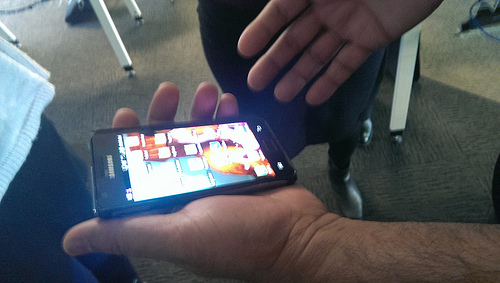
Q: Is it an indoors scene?
A: Yes, it is indoors.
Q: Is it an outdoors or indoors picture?
A: It is indoors.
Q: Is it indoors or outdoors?
A: It is indoors.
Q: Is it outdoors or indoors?
A: It is indoors.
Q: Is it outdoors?
A: No, it is indoors.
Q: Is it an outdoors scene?
A: No, it is indoors.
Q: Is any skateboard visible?
A: No, there are no skateboards.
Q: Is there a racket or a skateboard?
A: No, there are no skateboards or rackets.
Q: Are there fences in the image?
A: No, there are no fences.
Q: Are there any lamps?
A: Yes, there is a lamp.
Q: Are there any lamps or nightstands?
A: Yes, there is a lamp.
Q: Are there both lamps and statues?
A: No, there is a lamp but no statues.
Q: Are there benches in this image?
A: No, there are no benches.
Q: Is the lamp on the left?
A: Yes, the lamp is on the left of the image.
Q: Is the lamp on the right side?
A: No, the lamp is on the left of the image.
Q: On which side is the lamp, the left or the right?
A: The lamp is on the left of the image.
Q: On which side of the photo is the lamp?
A: The lamp is on the left of the image.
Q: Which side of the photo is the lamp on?
A: The lamp is on the left of the image.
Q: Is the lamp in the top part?
A: Yes, the lamp is in the top of the image.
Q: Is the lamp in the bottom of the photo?
A: No, the lamp is in the top of the image.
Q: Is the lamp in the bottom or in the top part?
A: The lamp is in the top of the image.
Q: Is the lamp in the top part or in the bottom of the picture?
A: The lamp is in the top of the image.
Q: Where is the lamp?
A: The lamp is on the floor.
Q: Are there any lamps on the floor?
A: Yes, there is a lamp on the floor.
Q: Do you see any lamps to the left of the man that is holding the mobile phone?
A: Yes, there is a lamp to the left of the man.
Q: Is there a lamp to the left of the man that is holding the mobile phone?
A: Yes, there is a lamp to the left of the man.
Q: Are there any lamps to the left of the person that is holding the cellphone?
A: Yes, there is a lamp to the left of the man.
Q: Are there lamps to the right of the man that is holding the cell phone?
A: No, the lamp is to the left of the man.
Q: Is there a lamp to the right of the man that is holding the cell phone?
A: No, the lamp is to the left of the man.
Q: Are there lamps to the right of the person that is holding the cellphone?
A: No, the lamp is to the left of the man.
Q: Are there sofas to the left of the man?
A: No, there is a lamp to the left of the man.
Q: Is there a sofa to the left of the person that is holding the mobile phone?
A: No, there is a lamp to the left of the man.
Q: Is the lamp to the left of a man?
A: Yes, the lamp is to the left of a man.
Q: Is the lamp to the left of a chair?
A: No, the lamp is to the left of a man.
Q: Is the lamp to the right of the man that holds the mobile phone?
A: No, the lamp is to the left of the man.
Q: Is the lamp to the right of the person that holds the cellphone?
A: No, the lamp is to the left of the man.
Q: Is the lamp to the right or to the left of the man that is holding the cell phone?
A: The lamp is to the left of the man.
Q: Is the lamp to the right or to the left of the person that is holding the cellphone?
A: The lamp is to the left of the man.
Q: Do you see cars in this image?
A: No, there are no cars.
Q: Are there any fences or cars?
A: No, there are no cars or fences.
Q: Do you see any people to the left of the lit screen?
A: Yes, there is a person to the left of the screen.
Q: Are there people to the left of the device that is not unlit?
A: Yes, there is a person to the left of the screen.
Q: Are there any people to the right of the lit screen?
A: No, the person is to the left of the screen.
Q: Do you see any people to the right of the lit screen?
A: No, the person is to the left of the screen.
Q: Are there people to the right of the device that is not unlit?
A: No, the person is to the left of the screen.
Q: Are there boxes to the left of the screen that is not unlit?
A: No, there is a person to the left of the screen.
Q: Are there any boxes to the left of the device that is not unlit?
A: No, there is a person to the left of the screen.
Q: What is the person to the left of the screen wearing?
A: The person is wearing a sweater.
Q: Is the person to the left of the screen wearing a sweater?
A: Yes, the person is wearing a sweater.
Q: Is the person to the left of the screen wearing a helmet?
A: No, the person is wearing a sweater.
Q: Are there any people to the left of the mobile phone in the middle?
A: Yes, there is a person to the left of the cell phone.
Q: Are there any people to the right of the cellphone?
A: No, the person is to the left of the cellphone.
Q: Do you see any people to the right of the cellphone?
A: No, the person is to the left of the cellphone.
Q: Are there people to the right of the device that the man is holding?
A: No, the person is to the left of the cellphone.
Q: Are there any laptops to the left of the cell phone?
A: No, there is a person to the left of the cell phone.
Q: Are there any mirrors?
A: No, there are no mirrors.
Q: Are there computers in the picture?
A: No, there are no computers.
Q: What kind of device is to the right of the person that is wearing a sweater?
A: The device is a screen.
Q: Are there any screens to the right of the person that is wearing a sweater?
A: Yes, there is a screen to the right of the person.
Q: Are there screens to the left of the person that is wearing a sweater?
A: No, the screen is to the right of the person.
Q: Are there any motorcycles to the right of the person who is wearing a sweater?
A: No, there is a screen to the right of the person.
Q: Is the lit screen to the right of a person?
A: Yes, the screen is to the right of a person.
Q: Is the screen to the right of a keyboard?
A: No, the screen is to the right of a person.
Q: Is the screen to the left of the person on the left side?
A: No, the screen is to the right of the person.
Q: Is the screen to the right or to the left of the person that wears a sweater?
A: The screen is to the right of the person.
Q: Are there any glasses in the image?
A: No, there are no glasses.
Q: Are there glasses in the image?
A: No, there are no glasses.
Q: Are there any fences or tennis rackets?
A: No, there are no fences or tennis rackets.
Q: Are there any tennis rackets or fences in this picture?
A: No, there are no fences or tennis rackets.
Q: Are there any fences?
A: No, there are no fences.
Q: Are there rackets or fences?
A: No, there are no fences or rackets.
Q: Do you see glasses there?
A: No, there are no glasses.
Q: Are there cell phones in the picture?
A: Yes, there is a cell phone.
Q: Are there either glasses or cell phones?
A: Yes, there is a cell phone.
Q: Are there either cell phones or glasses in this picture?
A: Yes, there is a cell phone.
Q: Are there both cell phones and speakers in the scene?
A: No, there is a cell phone but no speakers.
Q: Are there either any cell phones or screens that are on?
A: Yes, the cell phone is on.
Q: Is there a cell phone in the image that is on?
A: Yes, there is a cell phone that is on.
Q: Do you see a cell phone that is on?
A: Yes, there is a cell phone that is on.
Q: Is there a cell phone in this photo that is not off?
A: Yes, there is a cell phone that is on.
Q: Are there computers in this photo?
A: No, there are no computers.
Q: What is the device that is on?
A: The device is a cell phone.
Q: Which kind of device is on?
A: The device is a cell phone.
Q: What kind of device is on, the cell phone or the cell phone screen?
A: The cell phone is on.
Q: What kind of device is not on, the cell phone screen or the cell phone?
A: The screen is not on.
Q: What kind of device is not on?
A: The device is a screen.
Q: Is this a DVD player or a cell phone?
A: This is a cell phone.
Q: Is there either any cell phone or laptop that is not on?
A: No, there is a cell phone but it is on.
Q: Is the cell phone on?
A: Yes, the cell phone is on.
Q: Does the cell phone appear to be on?
A: Yes, the cell phone is on.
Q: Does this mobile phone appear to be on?
A: Yes, the mobile phone is on.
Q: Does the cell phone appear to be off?
A: No, the cell phone is on.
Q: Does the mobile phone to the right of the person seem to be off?
A: No, the mobile phone is on.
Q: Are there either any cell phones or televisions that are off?
A: No, there is a cell phone but it is on.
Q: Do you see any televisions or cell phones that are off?
A: No, there is a cell phone but it is on.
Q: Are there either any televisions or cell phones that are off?
A: No, there is a cell phone but it is on.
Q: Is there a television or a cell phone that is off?
A: No, there is a cell phone but it is on.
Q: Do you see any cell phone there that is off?
A: No, there is a cell phone but it is on.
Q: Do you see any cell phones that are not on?
A: No, there is a cell phone but it is on.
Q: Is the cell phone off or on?
A: The cell phone is on.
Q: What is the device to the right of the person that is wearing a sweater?
A: The device is a cell phone.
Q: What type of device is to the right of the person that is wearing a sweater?
A: The device is a cell phone.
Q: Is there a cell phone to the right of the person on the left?
A: Yes, there is a cell phone to the right of the person.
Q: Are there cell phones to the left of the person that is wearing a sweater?
A: No, the cell phone is to the right of the person.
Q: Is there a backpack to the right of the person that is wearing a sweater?
A: No, there is a cell phone to the right of the person.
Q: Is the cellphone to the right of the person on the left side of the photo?
A: Yes, the cellphone is to the right of the person.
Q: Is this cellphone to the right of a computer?
A: No, the cellphone is to the right of the person.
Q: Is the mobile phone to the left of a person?
A: No, the mobile phone is to the right of a person.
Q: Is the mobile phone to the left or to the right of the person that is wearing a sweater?
A: The mobile phone is to the right of the person.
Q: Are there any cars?
A: No, there are no cars.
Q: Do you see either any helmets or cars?
A: No, there are no cars or helmets.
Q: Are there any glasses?
A: No, there are no glasses.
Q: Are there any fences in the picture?
A: No, there are no fences.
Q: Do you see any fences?
A: No, there are no fences.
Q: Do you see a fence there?
A: No, there are no fences.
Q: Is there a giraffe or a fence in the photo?
A: No, there are no fences or giraffes.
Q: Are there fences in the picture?
A: No, there are no fences.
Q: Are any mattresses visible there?
A: No, there are no mattresses.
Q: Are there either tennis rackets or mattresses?
A: No, there are no mattresses or tennis rackets.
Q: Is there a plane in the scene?
A: No, there are no airplanes.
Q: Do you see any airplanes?
A: No, there are no airplanes.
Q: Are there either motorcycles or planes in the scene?
A: No, there are no planes or motorcycles.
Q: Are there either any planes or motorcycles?
A: No, there are no planes or motorcycles.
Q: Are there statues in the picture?
A: No, there are no statues.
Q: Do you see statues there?
A: No, there are no statues.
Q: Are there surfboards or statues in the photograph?
A: No, there are no statues or surfboards.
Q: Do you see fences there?
A: No, there are no fences.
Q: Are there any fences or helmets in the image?
A: No, there are no fences or helmets.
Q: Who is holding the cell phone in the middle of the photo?
A: The man is holding the cellphone.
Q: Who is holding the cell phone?
A: The man is holding the cellphone.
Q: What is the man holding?
A: The man is holding the mobile phone.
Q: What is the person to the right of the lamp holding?
A: The man is holding the mobile phone.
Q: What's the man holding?
A: The man is holding the mobile phone.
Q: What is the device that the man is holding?
A: The device is a cell phone.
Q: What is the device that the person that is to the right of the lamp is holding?
A: The device is a cell phone.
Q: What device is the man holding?
A: The man is holding the cell phone.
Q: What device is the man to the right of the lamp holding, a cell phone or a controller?
A: The man is holding a cell phone.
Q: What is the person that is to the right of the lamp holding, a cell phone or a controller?
A: The man is holding a cell phone.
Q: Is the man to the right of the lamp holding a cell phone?
A: Yes, the man is holding a cell phone.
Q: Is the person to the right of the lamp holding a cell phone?
A: Yes, the man is holding a cell phone.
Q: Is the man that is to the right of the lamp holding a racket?
A: No, the man is holding a cell phone.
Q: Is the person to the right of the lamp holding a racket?
A: No, the man is holding a cell phone.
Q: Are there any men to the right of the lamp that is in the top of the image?
A: Yes, there is a man to the right of the lamp.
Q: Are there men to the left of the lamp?
A: No, the man is to the right of the lamp.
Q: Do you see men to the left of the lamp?
A: No, the man is to the right of the lamp.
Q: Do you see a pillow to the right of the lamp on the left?
A: No, there is a man to the right of the lamp.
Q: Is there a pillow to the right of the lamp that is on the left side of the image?
A: No, there is a man to the right of the lamp.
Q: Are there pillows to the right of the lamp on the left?
A: No, there is a man to the right of the lamp.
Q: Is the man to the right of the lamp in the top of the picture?
A: Yes, the man is to the right of the lamp.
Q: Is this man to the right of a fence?
A: No, the man is to the right of the lamp.